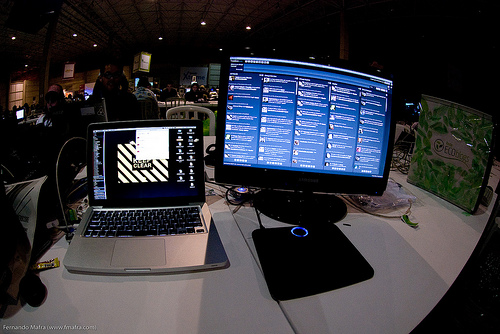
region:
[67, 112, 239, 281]
a silver laptop that is on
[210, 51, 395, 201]
black computer monitor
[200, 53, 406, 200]
lots of blue on the computer screen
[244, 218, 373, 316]
black mouse pad on the table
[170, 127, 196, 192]
small icons on the desktop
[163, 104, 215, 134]
top of a white chair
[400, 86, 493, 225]
green and white bag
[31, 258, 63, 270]
wrapper on the table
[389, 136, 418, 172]
a bunch of black wires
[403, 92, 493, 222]
bag on the table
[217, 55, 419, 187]
a dispaly of computer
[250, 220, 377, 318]
a small box in table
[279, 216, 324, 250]
light falling on table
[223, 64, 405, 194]
a display in the screen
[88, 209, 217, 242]
a laptop key board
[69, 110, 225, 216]
another display of screen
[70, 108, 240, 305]
a laptop on the table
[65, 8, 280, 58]
a group of lights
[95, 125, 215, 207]
a small box in display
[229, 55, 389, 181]
screen on the monitor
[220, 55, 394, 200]
monitor for the computer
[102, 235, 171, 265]
trackpad on the computer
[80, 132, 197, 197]
screen on the laptop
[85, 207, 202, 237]
keyboard on the laptop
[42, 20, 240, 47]
lights on the ceiling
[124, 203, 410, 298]
computers on the desk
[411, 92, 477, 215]
binder on the desk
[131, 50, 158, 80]
poster on the wall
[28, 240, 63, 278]
candy next to laptop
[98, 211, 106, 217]
black key on keyboard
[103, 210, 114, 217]
black key on keyboard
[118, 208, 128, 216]
black key on keyboard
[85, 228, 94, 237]
black key on keyboard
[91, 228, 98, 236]
black key on keyboard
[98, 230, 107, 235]
black key on keyboard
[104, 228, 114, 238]
black key on keyboard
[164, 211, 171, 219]
black key on keyboard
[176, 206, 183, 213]
black key on keyboard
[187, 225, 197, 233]
black key on keyboard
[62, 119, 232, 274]
A silver and black laptop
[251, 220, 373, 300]
A touch pad accesory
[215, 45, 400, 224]
A computer monitor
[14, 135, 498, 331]
Two white tables which were placed next to each other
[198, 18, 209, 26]
A ceiling light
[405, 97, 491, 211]
A white and green box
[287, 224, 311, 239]
A blue round part of the touch pad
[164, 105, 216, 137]
The top part of a white chair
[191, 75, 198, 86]
A person standing up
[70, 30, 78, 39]
Another ceiling light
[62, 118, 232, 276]
The laptop on the table